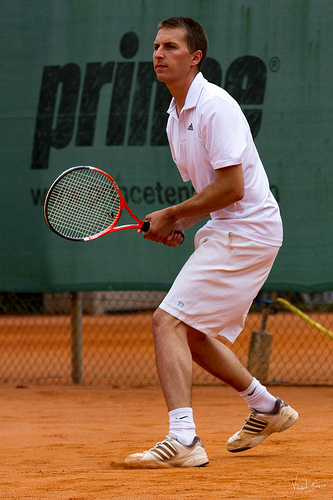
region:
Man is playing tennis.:
[41, 13, 311, 482]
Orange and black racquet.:
[37, 161, 184, 245]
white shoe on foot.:
[117, 434, 208, 469]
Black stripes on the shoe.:
[148, 441, 182, 462]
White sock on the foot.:
[161, 407, 200, 451]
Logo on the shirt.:
[183, 121, 196, 133]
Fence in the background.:
[0, 0, 329, 386]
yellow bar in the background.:
[273, 293, 332, 343]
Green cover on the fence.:
[1, 0, 332, 297]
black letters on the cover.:
[24, 21, 287, 177]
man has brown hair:
[166, 15, 229, 66]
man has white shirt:
[163, 87, 274, 213]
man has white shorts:
[174, 213, 273, 329]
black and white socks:
[221, 381, 280, 409]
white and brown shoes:
[229, 398, 292, 457]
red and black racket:
[28, 161, 161, 258]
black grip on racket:
[128, 216, 188, 247]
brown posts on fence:
[45, 293, 172, 374]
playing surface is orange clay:
[45, 408, 104, 496]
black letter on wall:
[30, 61, 81, 167]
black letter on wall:
[74, 59, 116, 149]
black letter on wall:
[102, 31, 134, 148]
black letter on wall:
[128, 60, 170, 149]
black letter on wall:
[226, 54, 263, 139]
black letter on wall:
[27, 184, 49, 203]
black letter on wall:
[87, 184, 100, 209]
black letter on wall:
[110, 184, 128, 202]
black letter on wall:
[128, 183, 143, 206]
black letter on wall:
[142, 186, 157, 204]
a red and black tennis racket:
[27, 146, 178, 259]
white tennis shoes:
[107, 400, 330, 464]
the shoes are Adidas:
[116, 412, 328, 477]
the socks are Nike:
[153, 365, 298, 447]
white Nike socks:
[156, 393, 206, 441]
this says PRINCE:
[31, 21, 290, 174]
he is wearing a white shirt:
[147, 68, 309, 243]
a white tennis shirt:
[152, 78, 298, 247]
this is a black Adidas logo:
[180, 116, 198, 130]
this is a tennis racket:
[25, 137, 203, 275]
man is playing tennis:
[82, 119, 274, 472]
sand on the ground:
[39, 424, 87, 483]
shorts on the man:
[189, 241, 258, 327]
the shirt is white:
[210, 117, 251, 148]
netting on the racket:
[48, 157, 126, 250]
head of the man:
[137, 14, 206, 92]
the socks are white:
[175, 424, 190, 441]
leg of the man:
[196, 347, 251, 390]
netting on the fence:
[87, 298, 135, 378]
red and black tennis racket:
[37, 165, 147, 238]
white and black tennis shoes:
[115, 403, 296, 475]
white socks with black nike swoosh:
[164, 380, 275, 441]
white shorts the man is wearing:
[157, 220, 273, 331]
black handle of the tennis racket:
[141, 220, 183, 246]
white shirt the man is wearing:
[160, 75, 287, 240]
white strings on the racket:
[53, 174, 122, 235]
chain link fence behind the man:
[3, 292, 324, 381]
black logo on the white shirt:
[183, 124, 194, 133]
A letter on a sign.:
[35, 57, 79, 170]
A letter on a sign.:
[68, 51, 113, 159]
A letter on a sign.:
[104, 23, 133, 150]